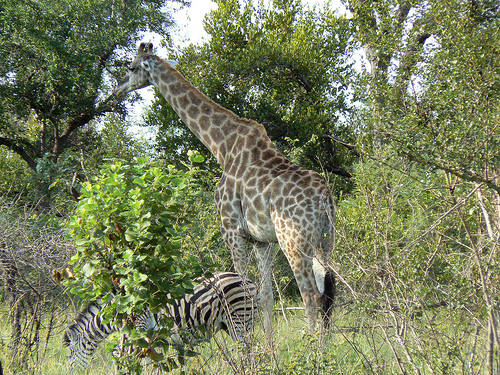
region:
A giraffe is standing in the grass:
[114, 32, 378, 348]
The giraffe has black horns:
[124, 32, 167, 74]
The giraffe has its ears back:
[111, 30, 200, 109]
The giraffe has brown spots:
[113, 27, 351, 356]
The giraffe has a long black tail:
[303, 212, 350, 319]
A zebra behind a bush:
[49, 262, 241, 364]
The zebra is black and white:
[51, 252, 276, 366]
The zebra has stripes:
[44, 257, 286, 365]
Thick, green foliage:
[20, 12, 477, 356]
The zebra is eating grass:
[51, 260, 257, 367]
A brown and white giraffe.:
[112, 36, 339, 351]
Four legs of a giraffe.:
[219, 219, 332, 359]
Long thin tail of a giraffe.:
[319, 198, 336, 336]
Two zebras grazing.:
[61, 269, 258, 374]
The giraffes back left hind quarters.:
[274, 210, 331, 358]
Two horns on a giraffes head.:
[133, 39, 154, 56]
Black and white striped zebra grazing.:
[112, 270, 261, 374]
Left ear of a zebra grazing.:
[63, 324, 78, 341]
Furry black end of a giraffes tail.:
[318, 267, 336, 329]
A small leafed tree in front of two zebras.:
[63, 146, 223, 369]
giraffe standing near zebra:
[127, 39, 338, 335]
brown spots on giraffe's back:
[236, 152, 253, 175]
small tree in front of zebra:
[67, 149, 235, 367]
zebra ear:
[62, 326, 75, 342]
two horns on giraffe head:
[136, 42, 154, 54]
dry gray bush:
[0, 186, 87, 373]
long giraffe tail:
[321, 186, 341, 328]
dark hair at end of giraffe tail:
[319, 271, 336, 326]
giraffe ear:
[139, 60, 153, 71]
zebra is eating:
[57, 274, 270, 371]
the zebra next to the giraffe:
[61, 270, 261, 372]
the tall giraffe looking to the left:
[115, 42, 339, 369]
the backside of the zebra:
[216, 270, 263, 370]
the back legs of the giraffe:
[276, 160, 338, 342]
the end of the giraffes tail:
[316, 270, 337, 333]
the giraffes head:
[114, 37, 156, 99]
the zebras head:
[58, 332, 92, 373]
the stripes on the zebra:
[203, 278, 240, 316]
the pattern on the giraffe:
[256, 168, 288, 203]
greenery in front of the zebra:
[69, 160, 192, 370]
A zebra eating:
[45, 260, 257, 372]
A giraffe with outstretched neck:
[105, 35, 346, 370]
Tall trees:
[0, 0, 130, 250]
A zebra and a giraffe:
[50, 35, 340, 365]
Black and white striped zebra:
[52, 265, 258, 360]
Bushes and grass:
[250, 175, 490, 370]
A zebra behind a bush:
[50, 150, 255, 365]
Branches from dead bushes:
[0, 180, 60, 365]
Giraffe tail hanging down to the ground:
[300, 175, 350, 325]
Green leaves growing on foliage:
[86, 166, 186, 326]